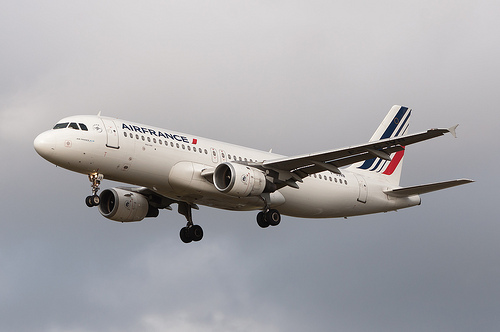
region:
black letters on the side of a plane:
[121, 111, 198, 144]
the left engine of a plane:
[196, 158, 268, 196]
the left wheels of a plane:
[248, 204, 279, 230]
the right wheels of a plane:
[174, 219, 209, 248]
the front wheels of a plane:
[83, 189, 112, 216]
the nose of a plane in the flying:
[28, 128, 61, 167]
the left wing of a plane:
[269, 112, 450, 181]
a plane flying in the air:
[28, 100, 481, 260]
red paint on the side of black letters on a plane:
[190, 128, 200, 147]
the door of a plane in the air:
[97, 115, 121, 155]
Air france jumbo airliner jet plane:
[24, 100, 481, 246]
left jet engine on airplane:
[210, 160, 276, 197]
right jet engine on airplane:
[95, 186, 160, 223]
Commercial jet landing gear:
[172, 202, 306, 244]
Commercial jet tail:
[349, 103, 479, 218]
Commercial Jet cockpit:
[33, 108, 110, 170]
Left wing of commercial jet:
[253, 123, 458, 189]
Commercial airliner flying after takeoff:
[0, 1, 497, 330]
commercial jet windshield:
[54, 121, 87, 130]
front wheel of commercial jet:
[82, 168, 105, 208]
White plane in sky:
[28, 101, 475, 245]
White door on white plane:
[102, 115, 119, 149]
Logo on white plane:
[119, 118, 196, 145]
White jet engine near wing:
[210, 158, 275, 198]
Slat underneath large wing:
[361, 143, 395, 163]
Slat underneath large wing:
[302, 155, 344, 177]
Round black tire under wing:
[267, 205, 282, 227]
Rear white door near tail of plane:
[354, 171, 368, 204]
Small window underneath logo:
[122, 129, 129, 139]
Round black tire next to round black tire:
[255, 210, 270, 228]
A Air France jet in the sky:
[34, 86, 476, 244]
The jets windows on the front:
[122, 128, 257, 169]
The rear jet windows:
[306, 167, 351, 187]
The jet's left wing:
[204, 127, 454, 199]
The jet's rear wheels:
[179, 203, 281, 246]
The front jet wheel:
[87, 171, 102, 211]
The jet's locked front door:
[102, 114, 120, 151]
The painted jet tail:
[362, 102, 413, 179]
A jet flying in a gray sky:
[0, 0, 497, 331]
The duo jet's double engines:
[97, 161, 267, 223]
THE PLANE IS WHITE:
[25, 95, 482, 253]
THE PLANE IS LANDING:
[27, 96, 479, 246]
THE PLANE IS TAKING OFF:
[25, 101, 477, 246]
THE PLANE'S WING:
[238, 110, 447, 197]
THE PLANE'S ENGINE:
[207, 157, 274, 200]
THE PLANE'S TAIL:
[346, 95, 425, 193]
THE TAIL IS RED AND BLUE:
[359, 95, 416, 177]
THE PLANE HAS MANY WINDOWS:
[118, 128, 349, 190]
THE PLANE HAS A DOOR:
[97, 112, 126, 155]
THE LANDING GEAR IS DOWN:
[80, 166, 285, 253]